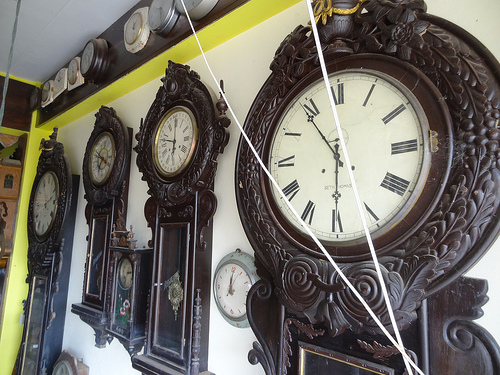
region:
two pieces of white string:
[271, 190, 434, 352]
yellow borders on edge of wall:
[10, 112, 72, 142]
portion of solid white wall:
[216, 51, 260, 73]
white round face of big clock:
[270, 69, 437, 239]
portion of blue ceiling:
[25, 20, 71, 55]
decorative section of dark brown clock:
[429, 26, 499, 113]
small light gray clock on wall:
[211, 247, 267, 336]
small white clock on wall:
[112, 3, 151, 51]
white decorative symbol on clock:
[163, 266, 194, 332]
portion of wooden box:
[3, 153, 26, 210]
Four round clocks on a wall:
[13, 30, 120, 111]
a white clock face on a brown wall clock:
[19, 123, 81, 281]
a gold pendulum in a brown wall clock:
[147, 219, 205, 336]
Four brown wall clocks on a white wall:
[16, 108, 215, 357]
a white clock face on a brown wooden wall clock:
[237, 41, 462, 269]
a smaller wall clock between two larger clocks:
[75, 95, 216, 367]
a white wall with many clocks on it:
[16, 8, 491, 369]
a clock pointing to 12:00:
[195, 241, 265, 335]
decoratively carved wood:
[256, 247, 498, 340]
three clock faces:
[20, 95, 225, 243]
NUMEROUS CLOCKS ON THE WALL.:
[22, 6, 495, 374]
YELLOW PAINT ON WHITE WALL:
[219, 16, 268, 27]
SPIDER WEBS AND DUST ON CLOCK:
[415, 111, 478, 183]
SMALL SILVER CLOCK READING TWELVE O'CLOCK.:
[212, 251, 261, 327]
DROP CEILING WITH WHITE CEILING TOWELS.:
[21, 11, 67, 62]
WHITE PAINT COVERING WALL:
[227, 56, 258, 76]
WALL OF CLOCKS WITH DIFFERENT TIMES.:
[32, 8, 487, 368]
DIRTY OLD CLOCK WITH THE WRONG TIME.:
[137, 51, 232, 373]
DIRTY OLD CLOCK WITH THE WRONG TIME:
[78, 106, 124, 347]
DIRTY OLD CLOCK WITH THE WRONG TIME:
[17, 131, 77, 369]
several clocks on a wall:
[14, 0, 496, 372]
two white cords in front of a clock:
[180, 0, 422, 373]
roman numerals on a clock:
[360, 82, 415, 210]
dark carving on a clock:
[451, 171, 491, 244]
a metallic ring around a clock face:
[177, 105, 197, 168]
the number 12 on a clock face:
[228, 263, 238, 275]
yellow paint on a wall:
[30, 121, 42, 148]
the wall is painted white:
[217, 327, 238, 365]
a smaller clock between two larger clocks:
[92, 192, 170, 364]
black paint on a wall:
[111, 54, 133, 66]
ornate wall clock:
[127, 56, 229, 371]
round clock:
[210, 247, 261, 327]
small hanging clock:
[102, 230, 152, 360]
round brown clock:
[75, 35, 112, 85]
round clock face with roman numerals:
[251, 56, 451, 256]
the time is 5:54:
[263, 57, 443, 254]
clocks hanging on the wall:
[5, 1, 495, 366]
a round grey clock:
[210, 245, 265, 332]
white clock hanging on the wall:
[115, 5, 151, 56]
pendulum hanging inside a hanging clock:
[164, 217, 189, 322]